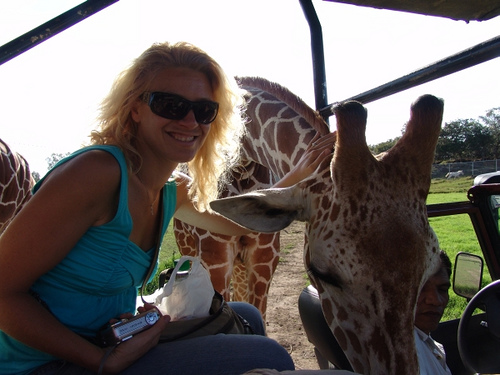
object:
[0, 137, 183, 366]
shirt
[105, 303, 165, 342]
camera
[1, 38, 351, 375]
woman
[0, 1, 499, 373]
vehicle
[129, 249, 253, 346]
bag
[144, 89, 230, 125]
sunglasses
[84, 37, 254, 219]
hair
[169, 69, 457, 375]
giraffe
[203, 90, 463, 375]
head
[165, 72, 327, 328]
body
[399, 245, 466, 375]
man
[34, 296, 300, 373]
jeans